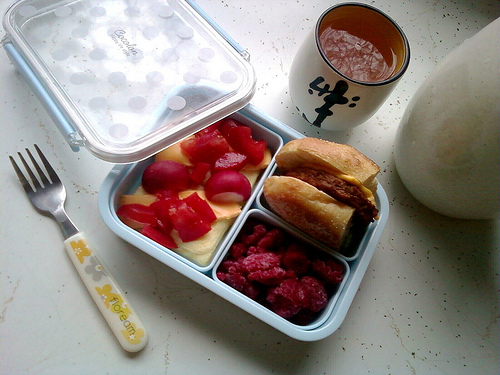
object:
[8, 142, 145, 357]
fork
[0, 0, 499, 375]
table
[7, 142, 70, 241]
fork prongs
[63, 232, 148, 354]
handle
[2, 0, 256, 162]
top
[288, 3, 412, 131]
cup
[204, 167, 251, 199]
food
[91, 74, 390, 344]
dish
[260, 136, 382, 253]
sandwich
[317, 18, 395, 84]
chocolate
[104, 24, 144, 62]
letters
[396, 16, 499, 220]
jar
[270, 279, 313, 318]
strawberries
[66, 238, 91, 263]
flower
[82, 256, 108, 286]
flower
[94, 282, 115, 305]
flower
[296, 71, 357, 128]
image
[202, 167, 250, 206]
radish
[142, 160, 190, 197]
radish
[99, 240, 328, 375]
shadow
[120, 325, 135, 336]
letters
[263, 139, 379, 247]
meat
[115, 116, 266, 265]
peppers